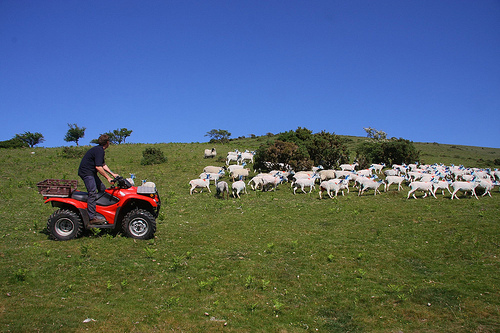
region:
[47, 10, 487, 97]
bright blue skies with no clouds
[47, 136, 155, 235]
a man riding a red four wheeler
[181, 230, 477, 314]
green grass on the hill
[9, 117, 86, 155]
trees in the background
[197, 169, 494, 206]
white cattle all bunched together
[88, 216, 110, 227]
boots being worn by the man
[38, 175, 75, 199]
a basket on the back of the four wheeler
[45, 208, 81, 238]
the back wheel of the four wheeler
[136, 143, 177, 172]
a shrub bush in the background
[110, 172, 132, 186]
the steering wheel of the vehicle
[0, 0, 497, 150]
A bright blue sky.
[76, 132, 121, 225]
A man on a ATV.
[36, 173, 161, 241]
An ATV on a hill.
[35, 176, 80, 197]
A brown basket on an ATV.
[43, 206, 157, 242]
Two black ATV tires.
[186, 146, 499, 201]
A bunch of sheep.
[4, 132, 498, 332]
A green grassy hillside.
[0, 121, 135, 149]
Trees on a hill.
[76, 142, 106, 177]
A mans black shirt.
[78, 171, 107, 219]
A pair of jeans.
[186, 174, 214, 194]
a sheep in the field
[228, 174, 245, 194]
a sheep in the field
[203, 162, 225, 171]
a sheep in the field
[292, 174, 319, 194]
a sheep in the field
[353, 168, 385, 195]
a sheep in the field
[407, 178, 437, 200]
a sheep in the field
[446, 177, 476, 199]
a sheep in the field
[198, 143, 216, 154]
a sheep in the field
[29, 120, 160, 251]
a man in a red truck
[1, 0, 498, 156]
a clear blue sky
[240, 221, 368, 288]
Grass is green color.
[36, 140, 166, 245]
One man is driving the truck.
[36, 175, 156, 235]
Truck is red color.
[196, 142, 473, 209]
Sheep are walking.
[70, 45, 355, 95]
Sky is blue color.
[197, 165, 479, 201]
Sheep are white color.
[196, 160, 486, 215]
Sheep are in grass.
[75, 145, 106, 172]
Man is wearing black shirt.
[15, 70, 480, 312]
Day time picture.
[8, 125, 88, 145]
Trees are green color.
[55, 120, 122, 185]
Young man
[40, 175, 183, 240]
Red ATV in field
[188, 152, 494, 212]
Herd of sheep in green pasture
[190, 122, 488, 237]
Herd of sheep grazing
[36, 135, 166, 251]
Young man riding an ATV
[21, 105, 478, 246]
Young man herding sheep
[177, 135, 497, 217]
Sheep eating grass in field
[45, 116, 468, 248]
Young man watching over herd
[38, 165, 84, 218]
Basket on back of ATV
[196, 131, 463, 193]
Trees giving shade to sheep